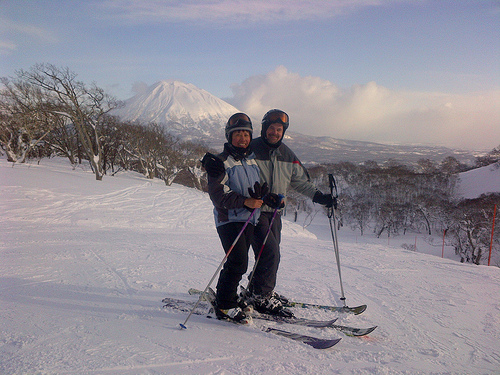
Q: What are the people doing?
A: Skiing.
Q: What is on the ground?
A: Snow.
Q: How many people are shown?
A: 2.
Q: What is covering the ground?
A: Snow.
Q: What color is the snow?
A: White.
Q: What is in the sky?
A: Clouds.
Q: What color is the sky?
A: Blue.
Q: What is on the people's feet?
A: Skis.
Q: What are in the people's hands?
A: Ski poles.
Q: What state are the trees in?
A: Bare.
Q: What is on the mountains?
A: Snow.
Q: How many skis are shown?
A: 4.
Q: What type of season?
A: Winter.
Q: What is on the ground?
A: Snow.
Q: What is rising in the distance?
A: A mountain.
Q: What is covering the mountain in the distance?
A: Snow.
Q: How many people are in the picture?
A: Two.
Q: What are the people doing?
A: Skiing.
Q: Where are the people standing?
A: A slope.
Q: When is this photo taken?
A: In the winter.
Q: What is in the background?
A: Trees.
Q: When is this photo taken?
A: Daytime.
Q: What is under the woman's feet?
A: Skis.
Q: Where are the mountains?
A: Behind the people.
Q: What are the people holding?
A: Poles.